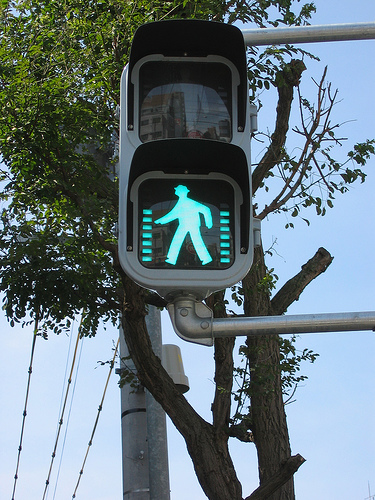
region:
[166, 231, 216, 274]
Green pants on walk way figure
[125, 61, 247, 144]
Section of walk way crossing that is not lit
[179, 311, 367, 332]
Metal pole holding up light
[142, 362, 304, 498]
Brown tree behind traffic light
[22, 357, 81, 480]
Utility lines behind traffic pole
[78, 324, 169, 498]
Utility pole behind traffic light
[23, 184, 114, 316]
Green Leaves on tree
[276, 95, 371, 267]
Small branches protruding from tree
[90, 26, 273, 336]
Cross walk traffic light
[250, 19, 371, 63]
Top pole holding cross way light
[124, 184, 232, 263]
a walking traffic sign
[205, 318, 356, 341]
a dark metal post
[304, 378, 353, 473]
part of the blue sky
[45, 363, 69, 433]
part of electricity wires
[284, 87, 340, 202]
part of a tree branch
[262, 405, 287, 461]
stem of a tree branch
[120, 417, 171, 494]
part of a thick tall metal post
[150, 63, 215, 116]
upper blank traffic light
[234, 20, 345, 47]
an upper metal post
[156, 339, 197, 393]
a bucket like cintainer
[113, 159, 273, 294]
Green walk signal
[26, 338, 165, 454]
Black barbed wire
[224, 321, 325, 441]
Green leaves on tree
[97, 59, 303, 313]
Green walk sign on black signal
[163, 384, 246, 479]
Leafless tree branch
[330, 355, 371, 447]
Clear sky at mid day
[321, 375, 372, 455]
Cloudless sky in the middle of the day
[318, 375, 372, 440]
Cloudless sky during the day time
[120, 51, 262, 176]
Reflection of the city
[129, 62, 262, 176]
Reflection of the city in signal light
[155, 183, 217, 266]
Picture of a green man walking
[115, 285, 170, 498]
Large metal gray pole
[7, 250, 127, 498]
Three power lines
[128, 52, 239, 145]
Camera for the cross walk thing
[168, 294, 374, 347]
Metal joint holding up the top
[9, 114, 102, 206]
Various green leaves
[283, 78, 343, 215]
Thin tree branches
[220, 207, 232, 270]
Small green dashes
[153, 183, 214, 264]
Green man on crosswalk device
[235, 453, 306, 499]
brown colored tree branch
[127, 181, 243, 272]
A green walk sign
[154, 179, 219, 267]
a green man on a walk sign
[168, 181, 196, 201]
head with hat on walk sign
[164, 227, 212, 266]
man's legs on walk sign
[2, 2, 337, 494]
A tall green tree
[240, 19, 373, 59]
metal pole holding the walk sign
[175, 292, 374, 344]
metal pole holding the walk sign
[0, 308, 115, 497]
power lines in the air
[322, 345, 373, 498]
blue sky in the background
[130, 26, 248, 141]
sign not lit up